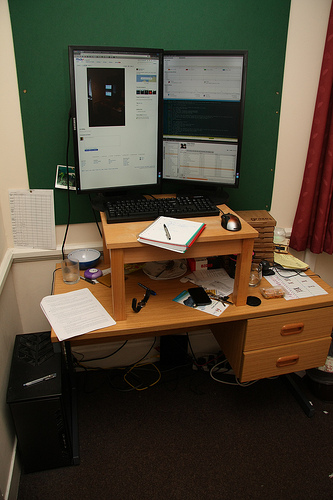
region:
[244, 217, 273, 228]
box on the desk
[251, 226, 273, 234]
box on the desk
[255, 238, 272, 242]
box on the desk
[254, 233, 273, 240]
box on the desk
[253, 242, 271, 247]
box on the desk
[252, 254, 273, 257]
box on the desk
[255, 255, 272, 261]
box on the desk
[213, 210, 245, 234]
mouse on the desk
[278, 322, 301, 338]
drawer pull on desk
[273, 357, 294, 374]
drawer pull on desk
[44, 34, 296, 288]
an unusual computer display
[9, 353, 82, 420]
a pen on the computer tower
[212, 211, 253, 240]
a mouse on the desk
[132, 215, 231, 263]
pen and pad of paper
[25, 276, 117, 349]
the report has been stapled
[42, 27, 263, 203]
two verticle computer monitors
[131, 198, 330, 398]
the desk is wooden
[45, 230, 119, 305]
the bowl is blue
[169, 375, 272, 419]
the floor is carpeted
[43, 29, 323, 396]
two monitor computer station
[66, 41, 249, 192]
the two monitors on the desk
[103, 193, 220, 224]
the black keyboard on the desk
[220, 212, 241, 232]
the mouse on the desk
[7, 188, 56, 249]
the paper hanging on the wall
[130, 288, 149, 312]
the watch on the desk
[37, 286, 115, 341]
the papers on the desk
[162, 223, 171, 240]
the pen on the notebook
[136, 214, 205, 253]
the notebook on the desk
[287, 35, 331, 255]
the red curtain hanging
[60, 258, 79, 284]
the empty cup on the desk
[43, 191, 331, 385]
Computer desk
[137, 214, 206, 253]
Notebook on top of the computer desk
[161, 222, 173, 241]
Pen on top of the notebook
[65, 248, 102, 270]
CD rack on the desk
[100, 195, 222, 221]
Keyboard for the computer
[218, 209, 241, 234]
Computer mouse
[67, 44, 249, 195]
Dual monitor screen for a computer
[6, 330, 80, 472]
Black computer processor on the ground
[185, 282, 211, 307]
Smart phone on the desk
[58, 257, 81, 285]
Used glass cup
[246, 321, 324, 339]
Wooden drawer on desk.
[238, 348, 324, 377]
Wooden drawer on desk.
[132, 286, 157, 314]
Black watch sitting on desk.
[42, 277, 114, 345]
White papers on edge of desk.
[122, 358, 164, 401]
Yellow cord laying on ground.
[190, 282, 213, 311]
Black cellphone sitting on desk.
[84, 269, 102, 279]
Purple inhaler sitting on desk.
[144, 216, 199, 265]
White notebook sitting on desk.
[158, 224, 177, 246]
Pen sitting on top of notebook.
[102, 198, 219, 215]
Black keyboard sitting on desk.